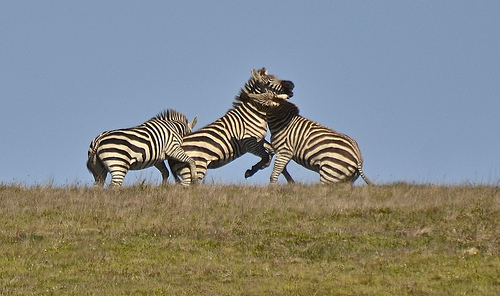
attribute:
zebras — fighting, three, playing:
[80, 62, 378, 191]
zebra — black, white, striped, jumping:
[253, 78, 363, 195]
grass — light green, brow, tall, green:
[211, 196, 386, 278]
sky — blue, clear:
[323, 18, 465, 123]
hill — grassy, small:
[308, 181, 495, 285]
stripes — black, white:
[305, 125, 348, 170]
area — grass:
[345, 200, 488, 291]